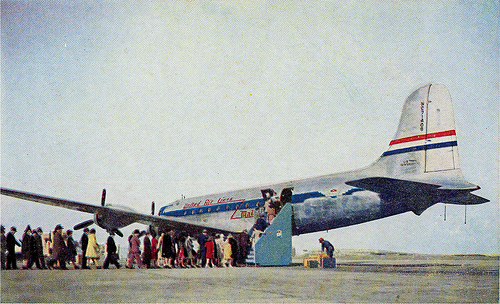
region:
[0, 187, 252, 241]
long wing of airplane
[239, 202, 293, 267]
blue stairs to airplane door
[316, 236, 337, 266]
person lifting suitcase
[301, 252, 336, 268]
luggage on tarmac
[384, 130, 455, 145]
red stripe on tail of airplane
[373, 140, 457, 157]
blue stripe on tail of airplane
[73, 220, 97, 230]
propeller blade under wing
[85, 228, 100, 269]
woman wearing yellow coat walking toward airplane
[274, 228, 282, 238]
sign on side of stairs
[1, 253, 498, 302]
ground is gray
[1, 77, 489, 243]
a large airplane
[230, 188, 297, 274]
staircase beside plane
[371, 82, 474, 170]
red, white, and blue stripes on plane's tail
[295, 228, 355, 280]
person bending over large objects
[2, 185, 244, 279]
people facing towards plane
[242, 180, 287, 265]
people climbing stairs towards plane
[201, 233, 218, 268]
girl wearing a red coat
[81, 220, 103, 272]
woman wearing a yellow coat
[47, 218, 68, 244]
man wearing a hat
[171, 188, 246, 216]
red text on plane's side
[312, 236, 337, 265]
man picking up luggage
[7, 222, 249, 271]
Line of people walking to get on plane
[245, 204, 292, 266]
Blue airplane steps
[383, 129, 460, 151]
Red white and blue tail stripes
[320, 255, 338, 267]
1 piece of blue luggage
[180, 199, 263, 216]
9 windows on a plane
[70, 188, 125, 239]
Black plane propellers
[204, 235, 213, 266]
Girl wearing red coat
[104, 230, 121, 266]
Man carrying black bag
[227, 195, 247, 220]
red z on side of plane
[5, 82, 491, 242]
A red and silver airplane.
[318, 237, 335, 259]
A man on the tarmac.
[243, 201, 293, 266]
Steps to the plane.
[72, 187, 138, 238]
A planes propeller.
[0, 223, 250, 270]
Lots of people in a row.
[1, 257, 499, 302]
A silver tarmac for a plane.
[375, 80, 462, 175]
A planes silver tail.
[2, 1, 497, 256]
A cloudy blue sky.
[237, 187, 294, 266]
People getting on a plane.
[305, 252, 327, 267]
A yellow table on tarmac.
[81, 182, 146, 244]
Propeller on plane.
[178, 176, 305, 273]
Passengers.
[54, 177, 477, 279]
Passengers loading the plane.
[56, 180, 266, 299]
On the tarmac of the air port.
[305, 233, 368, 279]
Man loading the luggage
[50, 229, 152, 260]
people going on vacation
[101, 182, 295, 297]
commuters going on plane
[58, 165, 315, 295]
wing of the plane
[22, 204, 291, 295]
lots of people getting on a plane.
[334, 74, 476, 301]
tail of the plane.